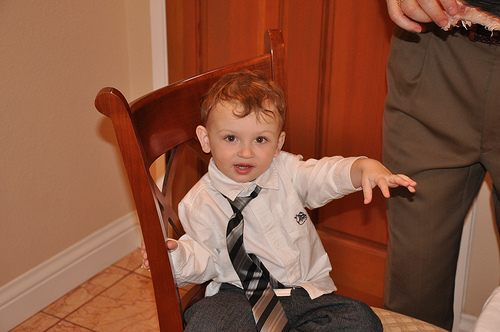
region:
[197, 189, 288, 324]
The boy is wearing a striped tie.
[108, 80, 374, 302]
The little boy is sitting in the chair.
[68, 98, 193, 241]
The chair is made of wood.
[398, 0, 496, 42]
A man has a piece of meat in his hand.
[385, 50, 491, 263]
The person is wearing pants.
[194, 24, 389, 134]
A brown door behind the person.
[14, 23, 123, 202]
The wall is beige.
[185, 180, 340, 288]
The little boy is wearing a white shirt.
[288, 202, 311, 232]
A logo on the shirt.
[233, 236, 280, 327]
The tie has black stripes.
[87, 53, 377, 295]
Little boy sitting in chair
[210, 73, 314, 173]
Little boy has red hair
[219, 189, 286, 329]
Little boy is wearing a tie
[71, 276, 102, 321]
The tile is large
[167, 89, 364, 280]
The little boy is posing for the camera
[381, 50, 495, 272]
Man is wearing khaki pants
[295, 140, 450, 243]
Little boy is holding out his hand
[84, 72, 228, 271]
he is sitting in a wooden chair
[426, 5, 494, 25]
Man is eating a sandwich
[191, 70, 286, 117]
Boy has a curl on front of head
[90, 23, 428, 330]
a toddler sits on a chair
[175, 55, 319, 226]
toddler has red hair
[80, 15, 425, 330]
chair is made of wood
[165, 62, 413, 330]
kid wearing a tie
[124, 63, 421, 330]
a kid wears a long sleeve shirt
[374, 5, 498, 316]
a person on side a toddler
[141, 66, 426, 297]
kid raise left hand forward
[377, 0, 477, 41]
a hand of a man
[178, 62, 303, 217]
kid is smiling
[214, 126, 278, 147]
eyes are black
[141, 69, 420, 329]
An infant sitting on a chair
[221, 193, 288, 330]
The infant wearing a tie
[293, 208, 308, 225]
A blackish decoration on the shirt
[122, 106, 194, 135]
The wooden back rest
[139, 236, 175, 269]
The hand holding on to the chair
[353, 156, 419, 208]
The hand raised up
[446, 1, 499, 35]
A piece of sandwich in the hand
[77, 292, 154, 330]
Brownish tiles on the floor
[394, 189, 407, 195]
Shadow cast by the hand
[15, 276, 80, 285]
White skirting along the wall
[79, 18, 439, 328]
a boy sitting in a chair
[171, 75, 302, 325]
a boy wearing a tie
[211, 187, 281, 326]
a black and silver tie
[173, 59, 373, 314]
a boy wearing a white shirt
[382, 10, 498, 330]
a pair of men's slacks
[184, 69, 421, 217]
a boy holding out his hand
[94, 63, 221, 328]
the back of a wooden chair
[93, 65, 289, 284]
a boy holding the back of a wooden chair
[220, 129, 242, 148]
the eye of a child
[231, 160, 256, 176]
the mouth of a child